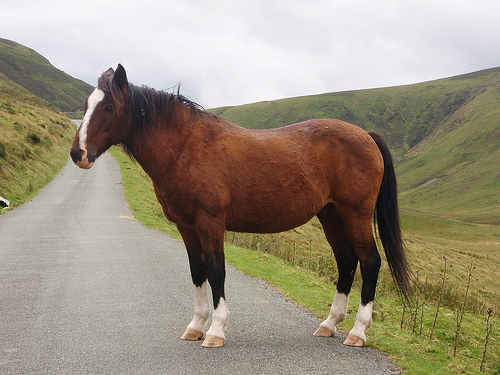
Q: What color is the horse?
A: Brown and white.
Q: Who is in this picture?
A: No one.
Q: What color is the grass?
A: Green.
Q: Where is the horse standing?
A: On a street.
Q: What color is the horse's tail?
A: Black.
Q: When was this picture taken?
A: Daytime.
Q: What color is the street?
A: Gray.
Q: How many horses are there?
A: One.